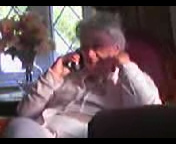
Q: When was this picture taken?
A: Day time.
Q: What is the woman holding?
A: A telephone.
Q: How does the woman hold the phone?
A: With her hand.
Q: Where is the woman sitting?
A: In a chair.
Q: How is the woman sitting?
A: Propped on her arm.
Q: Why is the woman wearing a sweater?
A: The woman is cold.